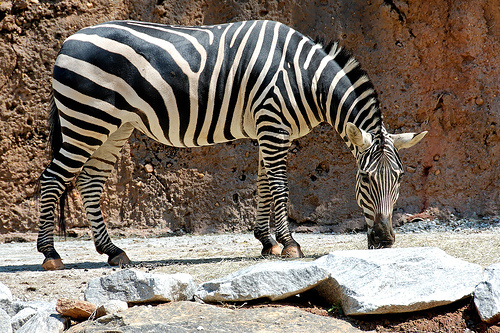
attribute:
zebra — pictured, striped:
[60, 27, 399, 240]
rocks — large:
[312, 246, 476, 308]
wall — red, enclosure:
[384, 20, 467, 83]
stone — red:
[380, 17, 495, 127]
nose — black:
[368, 219, 398, 245]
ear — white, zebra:
[396, 126, 433, 150]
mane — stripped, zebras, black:
[329, 43, 392, 125]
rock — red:
[355, 17, 492, 70]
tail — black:
[47, 104, 62, 150]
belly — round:
[143, 122, 249, 152]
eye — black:
[358, 169, 372, 185]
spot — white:
[225, 54, 242, 91]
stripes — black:
[177, 25, 277, 58]